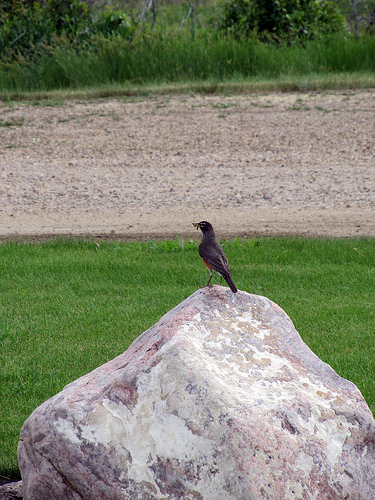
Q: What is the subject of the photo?
A: Bird.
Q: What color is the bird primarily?
A: Black.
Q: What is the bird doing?
A: Perching.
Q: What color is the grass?
A: Green.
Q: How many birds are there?
A: One.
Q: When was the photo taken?
A: Daytime.